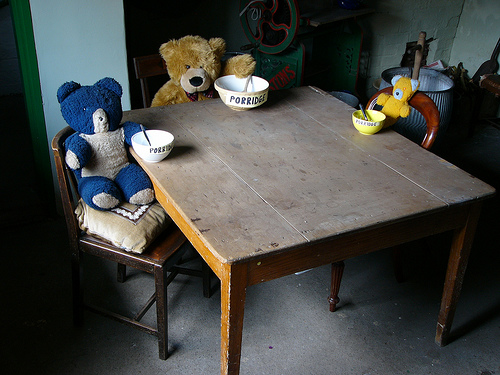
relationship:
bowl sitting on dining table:
[351, 109, 388, 136] [121, 83, 497, 374]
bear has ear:
[56, 77, 155, 212] [92, 76, 123, 99]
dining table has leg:
[121, 83, 497, 374] [220, 259, 249, 375]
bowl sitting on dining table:
[130, 129, 174, 164] [121, 83, 497, 374]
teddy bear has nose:
[150, 34, 257, 106] [188, 76, 204, 88]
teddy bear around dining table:
[150, 34, 257, 106] [121, 83, 497, 374]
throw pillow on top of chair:
[73, 195, 170, 255] [50, 125, 212, 360]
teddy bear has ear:
[376, 74, 420, 131] [410, 78, 421, 94]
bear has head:
[56, 77, 155, 212] [56, 76, 123, 134]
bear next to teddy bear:
[56, 77, 155, 212] [150, 34, 257, 106]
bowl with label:
[213, 74, 271, 113] [225, 89, 269, 108]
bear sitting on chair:
[56, 77, 155, 212] [50, 125, 212, 360]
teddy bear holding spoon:
[150, 34, 257, 106] [240, 73, 253, 94]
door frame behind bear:
[9, 0, 58, 224] [56, 77, 155, 212]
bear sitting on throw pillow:
[56, 77, 155, 212] [73, 195, 170, 255]